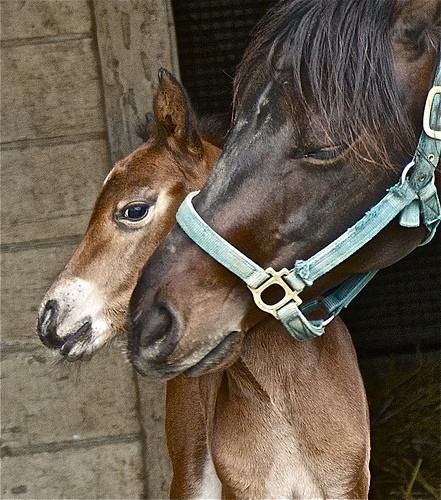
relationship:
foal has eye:
[33, 62, 373, 498] [119, 202, 153, 227]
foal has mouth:
[33, 62, 373, 498] [40, 317, 95, 360]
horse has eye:
[126, 3, 437, 383] [292, 133, 362, 172]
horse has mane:
[126, 3, 437, 383] [233, 0, 432, 173]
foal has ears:
[33, 62, 373, 498] [157, 67, 204, 161]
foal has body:
[33, 62, 373, 498] [142, 299, 368, 496]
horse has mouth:
[126, 3, 437, 383] [132, 329, 243, 382]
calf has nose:
[36, 61, 375, 499] [30, 302, 61, 341]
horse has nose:
[126, 3, 437, 383] [117, 284, 188, 372]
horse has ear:
[126, 3, 437, 383] [392, 4, 439, 51]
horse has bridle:
[126, 3, 437, 383] [173, 57, 438, 340]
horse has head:
[126, 3, 437, 383] [125, 1, 439, 380]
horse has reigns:
[126, 3, 437, 383] [177, 59, 440, 344]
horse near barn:
[126, 3, 437, 383] [4, 0, 438, 500]